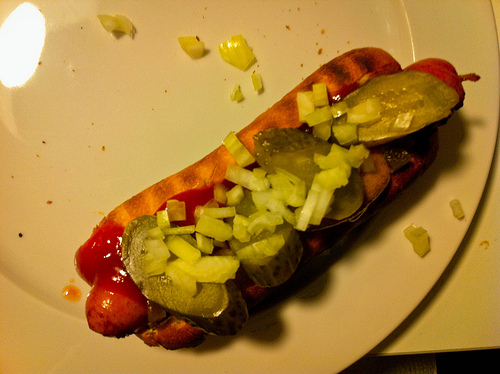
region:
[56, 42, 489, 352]
a hot dog on a white dish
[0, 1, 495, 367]
dish is flat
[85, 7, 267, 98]
diced onions over a dish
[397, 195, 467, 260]
diced onions on edge of dish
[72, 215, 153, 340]
ketchup over a hot dog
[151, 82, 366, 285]
diced onions over a hot dog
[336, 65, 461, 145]
slice of pickle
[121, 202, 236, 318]
diced onions on slice of pickle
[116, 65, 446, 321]
slices of pickles over hot dog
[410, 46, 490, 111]
hot dog under pickles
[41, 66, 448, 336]
hot dog inside bun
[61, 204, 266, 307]
ketchup on the bun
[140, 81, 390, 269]
onions on the hot dog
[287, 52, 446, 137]
pickles on the hot dog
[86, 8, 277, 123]
onions on the plate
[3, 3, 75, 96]
light shining on plate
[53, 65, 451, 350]
hot dog bun is toasted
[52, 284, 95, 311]
ketchup on the plate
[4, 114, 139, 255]
bread crumbs on plate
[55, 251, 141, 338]
hot dog sticking out of bun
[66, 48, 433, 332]
hot dog on plate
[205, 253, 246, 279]
diced onion on hot dog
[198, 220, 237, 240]
diced onion on hot dog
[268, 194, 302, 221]
diced onion on hot dog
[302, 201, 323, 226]
diced onion on hot dog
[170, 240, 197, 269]
diced onion on hot dog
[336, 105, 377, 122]
diced onion on hot dog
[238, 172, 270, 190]
diced onion on hot dog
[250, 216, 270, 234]
diced onion on hot dog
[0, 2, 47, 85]
the reflection of a light on a plate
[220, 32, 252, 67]
a piece of onion on a plate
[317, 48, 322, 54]
a bread crumb on a plate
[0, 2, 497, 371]
a round white plate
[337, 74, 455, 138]
a pickle slice on a hotdog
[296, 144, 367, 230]
onions on a pickle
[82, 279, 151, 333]
a hotdog in a bun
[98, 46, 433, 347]
a bun on a plate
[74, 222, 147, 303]
ketchup on a hotdog and bun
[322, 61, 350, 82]
a burn mark on a bun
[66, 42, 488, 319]
hot dog with toppings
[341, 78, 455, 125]
jalepeno on hot dog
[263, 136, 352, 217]
jalepeno on hot dog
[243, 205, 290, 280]
jalepeno on hot dog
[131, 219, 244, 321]
jalepeno on hot dog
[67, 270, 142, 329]
end of the hot dog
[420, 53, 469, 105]
end of the hot dog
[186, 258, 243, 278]
onion on the hot dog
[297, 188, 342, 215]
onion on the hot dog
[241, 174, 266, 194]
onion on the hot dog